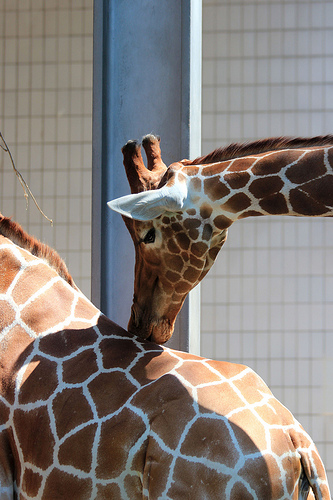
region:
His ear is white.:
[102, 185, 182, 225]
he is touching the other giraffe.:
[97, 172, 332, 358]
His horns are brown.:
[111, 141, 167, 183]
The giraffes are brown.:
[2, 115, 302, 459]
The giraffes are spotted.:
[9, 132, 326, 478]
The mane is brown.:
[183, 137, 328, 174]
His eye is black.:
[131, 229, 161, 248]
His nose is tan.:
[119, 293, 141, 334]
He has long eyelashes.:
[135, 225, 162, 254]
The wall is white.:
[205, 225, 323, 435]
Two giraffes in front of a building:
[0, 130, 329, 496]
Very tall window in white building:
[91, 0, 198, 354]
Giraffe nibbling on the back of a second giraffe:
[118, 131, 328, 340]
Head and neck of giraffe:
[105, 130, 328, 341]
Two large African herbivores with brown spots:
[0, 132, 330, 498]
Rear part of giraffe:
[1, 213, 332, 498]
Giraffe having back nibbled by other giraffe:
[0, 213, 330, 499]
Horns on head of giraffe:
[121, 132, 167, 189]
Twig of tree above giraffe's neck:
[0, 132, 54, 225]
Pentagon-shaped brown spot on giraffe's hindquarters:
[196, 379, 244, 416]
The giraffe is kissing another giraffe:
[103, 119, 260, 358]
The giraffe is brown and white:
[9, 293, 293, 428]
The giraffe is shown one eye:
[100, 213, 178, 267]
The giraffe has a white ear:
[118, 171, 220, 252]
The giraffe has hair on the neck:
[168, 140, 315, 169]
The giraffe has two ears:
[98, 124, 190, 177]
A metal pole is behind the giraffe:
[83, 18, 319, 66]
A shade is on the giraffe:
[7, 275, 213, 491]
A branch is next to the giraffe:
[8, 133, 46, 252]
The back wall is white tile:
[17, 110, 95, 181]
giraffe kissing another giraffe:
[66, 105, 309, 458]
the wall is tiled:
[225, 257, 329, 408]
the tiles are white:
[250, 296, 331, 407]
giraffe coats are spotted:
[62, 363, 228, 494]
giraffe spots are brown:
[39, 352, 149, 439]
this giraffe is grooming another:
[74, 94, 249, 407]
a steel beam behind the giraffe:
[65, 209, 260, 391]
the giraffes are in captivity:
[46, 232, 250, 411]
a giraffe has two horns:
[85, 120, 222, 227]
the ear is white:
[66, 101, 252, 363]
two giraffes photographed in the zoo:
[7, 53, 296, 490]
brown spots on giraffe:
[50, 374, 125, 465]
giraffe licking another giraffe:
[87, 125, 226, 369]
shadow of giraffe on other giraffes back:
[10, 311, 261, 495]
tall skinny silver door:
[102, 0, 194, 318]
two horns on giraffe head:
[116, 125, 170, 193]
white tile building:
[213, 10, 303, 127]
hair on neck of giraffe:
[186, 131, 329, 178]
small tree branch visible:
[4, 114, 57, 228]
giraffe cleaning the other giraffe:
[111, 134, 234, 367]